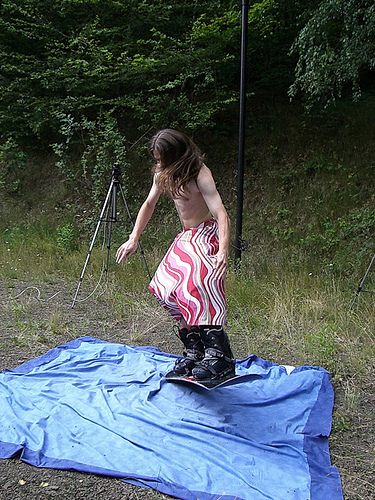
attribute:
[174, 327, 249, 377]
boots — black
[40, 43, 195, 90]
leaves — green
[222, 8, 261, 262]
pole — black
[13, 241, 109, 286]
grass — tall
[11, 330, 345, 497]
blanket — blue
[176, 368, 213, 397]
snowboard — black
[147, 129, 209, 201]
hair — long, brown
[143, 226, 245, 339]
skirt — striped, red